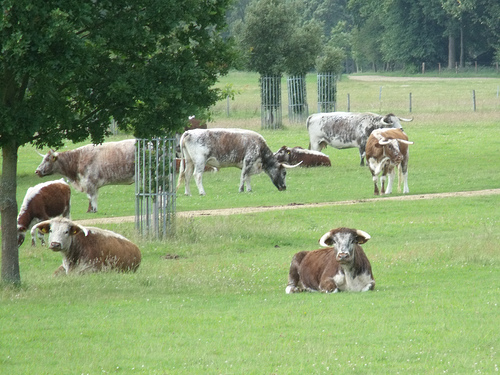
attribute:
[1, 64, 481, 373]
field — open, grassy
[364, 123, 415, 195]
animal — large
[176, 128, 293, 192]
bull — brown, white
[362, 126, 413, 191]
bull — brown, white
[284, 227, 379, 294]
bull — brown, white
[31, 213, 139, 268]
bull — brown, white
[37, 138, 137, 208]
bull — brown, white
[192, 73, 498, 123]
fence — property line-placed, short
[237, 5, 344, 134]
trees — short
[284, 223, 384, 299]
bull — white, brown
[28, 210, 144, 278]
bull — brown, white